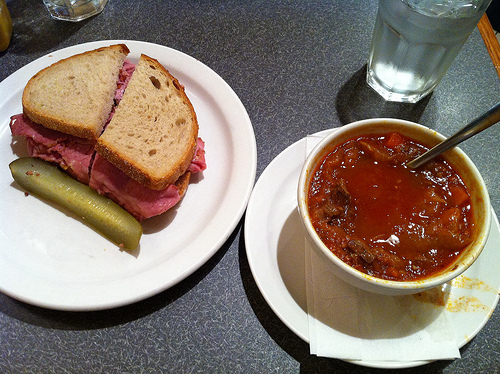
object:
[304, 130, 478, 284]
chili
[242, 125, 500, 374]
plate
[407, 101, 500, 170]
spoon